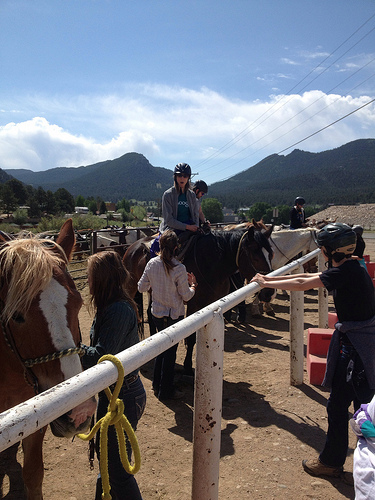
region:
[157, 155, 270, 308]
a woman on a horse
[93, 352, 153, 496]
a yellow knotted rope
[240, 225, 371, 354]
person holding a fence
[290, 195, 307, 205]
a black helmet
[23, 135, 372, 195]
small chain of mountains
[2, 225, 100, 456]
a brown and white horse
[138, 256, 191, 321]
woman wearing a white long sleeve shirt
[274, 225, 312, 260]
a white horse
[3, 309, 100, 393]
a harness on a horse's nose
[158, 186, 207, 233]
woman wearing a gray cardigan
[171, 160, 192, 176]
the black helmet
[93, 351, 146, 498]
a yellow rope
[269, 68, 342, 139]
the power lines overhead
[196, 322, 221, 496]
the white fence post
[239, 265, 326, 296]
Hands holding onto the rail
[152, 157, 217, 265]
people on horseback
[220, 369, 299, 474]
the shadows under the railing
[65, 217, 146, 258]
A herd of horses in the kennel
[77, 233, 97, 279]
the gate on the fence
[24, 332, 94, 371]
the rope on the horses face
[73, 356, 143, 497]
yellow rope tied to bar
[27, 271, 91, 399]
white stripe on horse's head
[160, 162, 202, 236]
woman on a horse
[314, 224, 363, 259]
helmet on boy's head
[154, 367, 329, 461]
shadow on the ground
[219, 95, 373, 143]
white fluffy clouds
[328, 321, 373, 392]
sweatshirt tied around waist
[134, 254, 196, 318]
white long sleeve shirt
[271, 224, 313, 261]
neck of white horse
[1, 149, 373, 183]
mountains covered with trees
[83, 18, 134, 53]
blue sky above the ground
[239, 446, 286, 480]
brown dirt under people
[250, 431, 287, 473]
rocks on the ground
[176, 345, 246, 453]
pole above the ground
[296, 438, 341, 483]
shoe on the man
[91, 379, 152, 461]
yellow rope on pole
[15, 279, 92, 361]
white and brown horse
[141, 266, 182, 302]
shirt on the lady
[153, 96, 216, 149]
clouds in the sky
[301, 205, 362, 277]
helmet on the kid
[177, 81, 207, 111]
part of a cloud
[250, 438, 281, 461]
part of a ground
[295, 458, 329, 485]
edge of a shoe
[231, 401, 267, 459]
part of a shade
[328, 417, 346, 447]
part of a trouser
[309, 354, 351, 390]
part of a sweater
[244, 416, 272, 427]
edge of a shade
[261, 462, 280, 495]
part of a ground